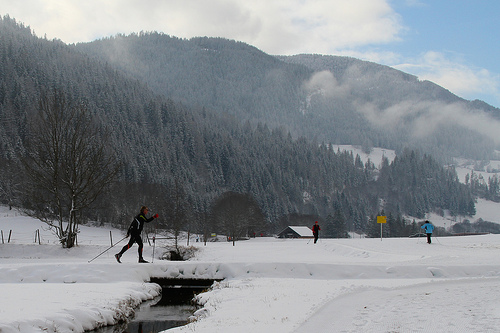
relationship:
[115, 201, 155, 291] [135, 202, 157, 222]
person has head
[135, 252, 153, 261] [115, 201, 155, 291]
shoe on person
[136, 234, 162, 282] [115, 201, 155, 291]
leg of person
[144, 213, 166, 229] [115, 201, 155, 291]
arm of person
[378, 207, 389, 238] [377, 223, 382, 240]
sign on post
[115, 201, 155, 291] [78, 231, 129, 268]
person with pole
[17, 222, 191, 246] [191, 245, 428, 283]
fence in snow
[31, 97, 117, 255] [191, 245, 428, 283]
tree in snow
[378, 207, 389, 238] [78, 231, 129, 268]
sign on pole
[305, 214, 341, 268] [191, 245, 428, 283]
man in snow